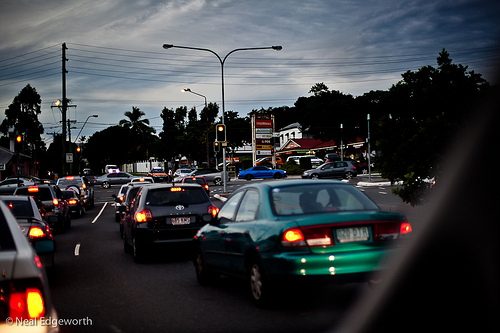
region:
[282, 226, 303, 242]
red taillight on car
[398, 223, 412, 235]
red taillight on car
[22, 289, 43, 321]
red taillight on car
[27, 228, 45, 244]
red taillight on car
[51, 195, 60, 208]
red taillight on car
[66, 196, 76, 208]
red taillight on car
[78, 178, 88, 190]
red taillight on car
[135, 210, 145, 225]
red taillight on car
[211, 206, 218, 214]
red taillight on car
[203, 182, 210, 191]
red taillight on car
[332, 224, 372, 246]
License plate on rear of green car.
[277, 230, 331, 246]
tail lights on green car.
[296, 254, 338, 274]
Lights reflecting on car.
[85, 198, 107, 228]
White line on middle of street.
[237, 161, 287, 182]
Blue car going right.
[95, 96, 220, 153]
Thick trees in the background.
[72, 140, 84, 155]
Red traffic stop light.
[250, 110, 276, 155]
Business signs for shopping center.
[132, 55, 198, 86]
Electrical wires hanging from poles.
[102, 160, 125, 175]
White SUV coming straight .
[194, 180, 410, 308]
green car on street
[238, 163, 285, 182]
blue car on street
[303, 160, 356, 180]
green car on street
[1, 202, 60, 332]
silver car on street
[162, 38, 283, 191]
grey metal street lamp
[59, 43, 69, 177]
brown wooden electrical pole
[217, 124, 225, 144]
stop light on post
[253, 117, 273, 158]
store signs on post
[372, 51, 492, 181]
tree with green leaves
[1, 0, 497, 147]
White clouds in the sky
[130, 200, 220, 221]
Two red rear lights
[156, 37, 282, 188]
A tall street lamp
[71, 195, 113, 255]
White lines are on the road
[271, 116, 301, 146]
A building is white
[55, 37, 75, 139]
A tall telephone pole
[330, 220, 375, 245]
A white license plate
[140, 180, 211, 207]
Back window of a car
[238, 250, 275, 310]
A black round tire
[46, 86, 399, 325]
view was taken in the street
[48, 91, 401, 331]
picture wa s taken at nite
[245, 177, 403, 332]
the car is grreen in color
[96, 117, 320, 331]
the cars are moviing is a line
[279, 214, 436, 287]
the car lights are on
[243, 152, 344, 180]
the cars are parked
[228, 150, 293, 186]
the car is blue in color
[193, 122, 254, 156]
the street lights are on